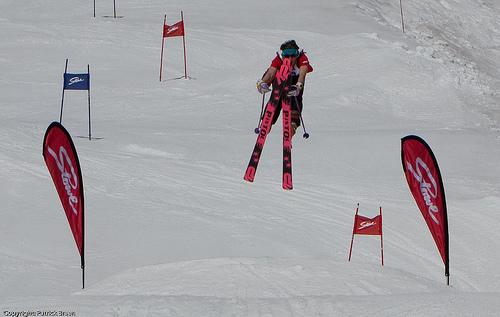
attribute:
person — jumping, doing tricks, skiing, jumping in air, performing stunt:
[243, 40, 313, 191]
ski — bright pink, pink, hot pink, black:
[243, 64, 288, 182]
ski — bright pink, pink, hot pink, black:
[281, 57, 294, 190]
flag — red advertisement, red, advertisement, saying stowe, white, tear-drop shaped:
[42, 121, 85, 290]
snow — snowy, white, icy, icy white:
[0, 0, 499, 317]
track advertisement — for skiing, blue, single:
[59, 58, 91, 141]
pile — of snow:
[72, 255, 462, 299]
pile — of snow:
[446, 195, 499, 223]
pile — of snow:
[359, 31, 460, 94]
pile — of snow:
[229, 26, 327, 48]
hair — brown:
[280, 40, 307, 59]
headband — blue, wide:
[281, 48, 299, 55]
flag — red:
[159, 11, 188, 83]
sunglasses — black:
[281, 53, 299, 58]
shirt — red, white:
[269, 50, 313, 85]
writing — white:
[46, 144, 78, 215]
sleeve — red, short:
[297, 52, 313, 74]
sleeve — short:
[270, 56, 283, 73]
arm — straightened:
[286, 53, 308, 98]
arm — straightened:
[257, 51, 281, 93]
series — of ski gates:
[60, 0, 384, 267]